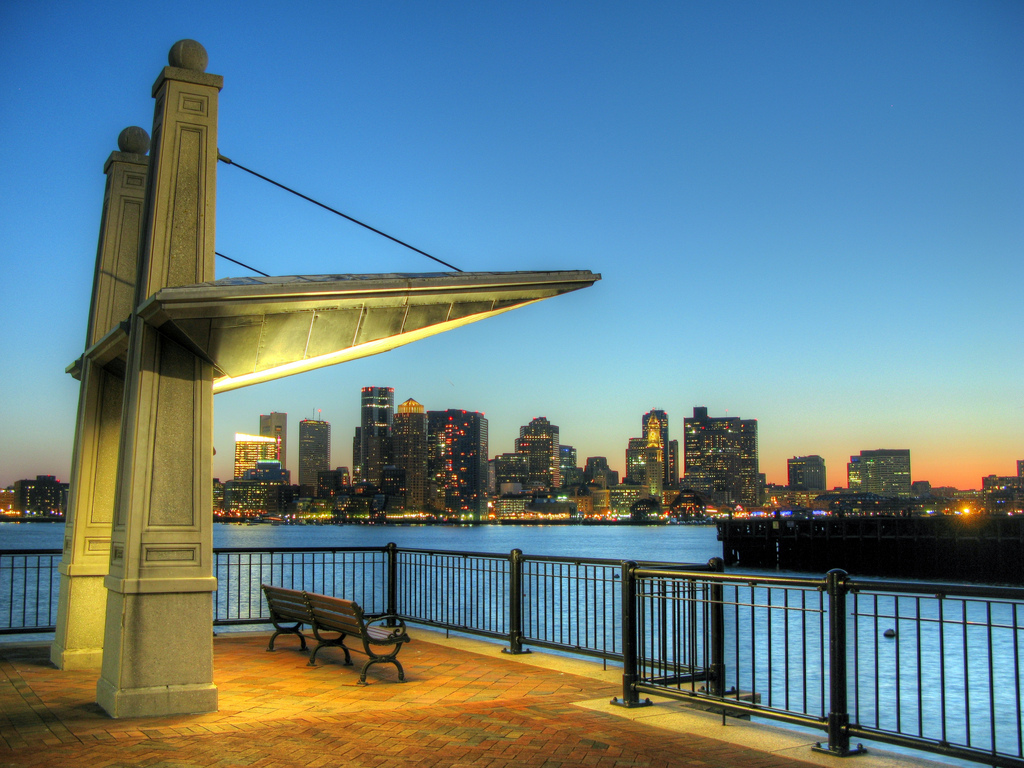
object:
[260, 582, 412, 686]
bench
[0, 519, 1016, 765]
river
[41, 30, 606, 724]
structure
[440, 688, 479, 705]
bricks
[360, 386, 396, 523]
skyscrapers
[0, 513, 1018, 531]
skyline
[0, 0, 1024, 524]
background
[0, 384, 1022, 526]
big city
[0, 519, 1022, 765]
calm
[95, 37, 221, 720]
concrete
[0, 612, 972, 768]
dock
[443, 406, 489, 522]
building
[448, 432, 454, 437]
lights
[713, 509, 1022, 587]
boat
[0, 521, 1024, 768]
waterway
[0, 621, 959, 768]
concrete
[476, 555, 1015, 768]
viewing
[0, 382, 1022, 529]
cityscape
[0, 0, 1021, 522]
distance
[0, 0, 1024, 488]
sunset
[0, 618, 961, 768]
down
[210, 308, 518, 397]
light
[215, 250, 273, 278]
wires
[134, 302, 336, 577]
up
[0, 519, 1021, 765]
water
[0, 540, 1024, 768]
fence